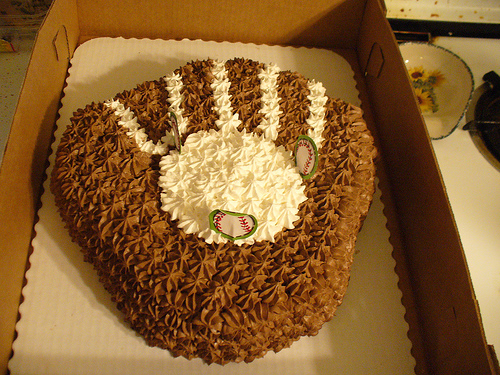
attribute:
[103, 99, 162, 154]
icing —  white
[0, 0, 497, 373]
delivery box —  for delivery,  brown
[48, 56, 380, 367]
frosting —  chocolate,  thick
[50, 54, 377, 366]
cake — of ball glove,  mitt shaped, frosting, decoration, baseball, frosted, shape, mitt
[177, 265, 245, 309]
icing —  brown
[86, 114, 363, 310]
frosting — chocolate and white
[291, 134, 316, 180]
baseball decoration — of baseball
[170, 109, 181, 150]
decoration — of baseball,  three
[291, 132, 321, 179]
decoration — of baseball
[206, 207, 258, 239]
decoration — of baseball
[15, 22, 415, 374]
paper —  white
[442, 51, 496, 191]
stove top —  white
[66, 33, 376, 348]
border —  green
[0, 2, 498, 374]
box —  cardboard,  brown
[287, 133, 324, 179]
decoration — of Baseball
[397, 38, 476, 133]
tan bowl —  tan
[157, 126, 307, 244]
frosting —  white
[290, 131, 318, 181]
decoration —  of baseball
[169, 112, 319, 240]
decoration — of baseball,  three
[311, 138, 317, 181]
border —  around,  green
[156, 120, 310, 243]
circle —  white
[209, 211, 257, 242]
decoration — of Baseball 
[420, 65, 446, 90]
daisy —  yellow 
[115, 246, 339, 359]
frosting —  brown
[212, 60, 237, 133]
frosting —   white